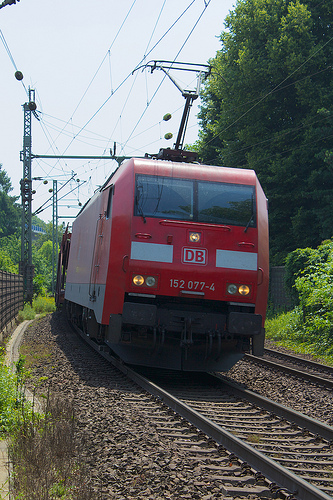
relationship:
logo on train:
[183, 244, 206, 270] [70, 156, 281, 367]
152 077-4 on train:
[162, 277, 222, 294] [70, 156, 281, 367]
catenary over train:
[108, 67, 183, 135] [70, 156, 281, 367]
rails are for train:
[55, 304, 330, 497] [70, 156, 281, 367]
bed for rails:
[258, 401, 302, 413] [55, 304, 330, 497]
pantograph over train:
[102, 94, 153, 128] [70, 156, 281, 367]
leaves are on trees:
[251, 96, 306, 141] [248, 106, 325, 235]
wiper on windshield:
[156, 210, 175, 222] [155, 179, 243, 225]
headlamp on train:
[180, 227, 205, 244] [70, 156, 281, 367]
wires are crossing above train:
[121, 21, 211, 49] [70, 156, 281, 367]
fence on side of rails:
[6, 288, 22, 305] [55, 304, 330, 497]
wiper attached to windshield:
[156, 210, 175, 222] [155, 179, 243, 225]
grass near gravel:
[245, 323, 303, 346] [282, 347, 300, 367]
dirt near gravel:
[34, 402, 86, 438] [282, 347, 300, 367]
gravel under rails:
[282, 347, 300, 367] [55, 304, 330, 497]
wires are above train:
[121, 21, 211, 49] [70, 156, 281, 367]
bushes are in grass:
[18, 286, 67, 314] [245, 323, 303, 346]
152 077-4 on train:
[167, 278, 218, 292] [70, 156, 281, 367]